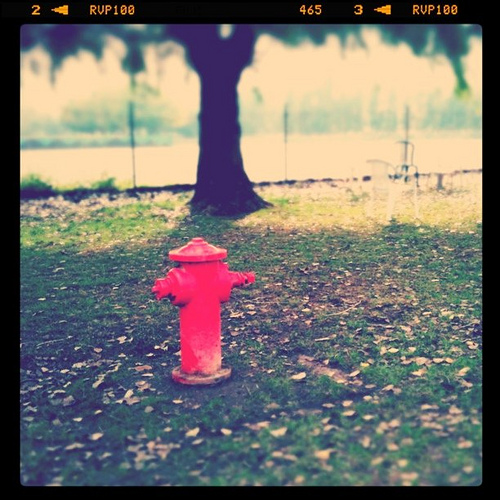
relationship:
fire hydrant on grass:
[142, 232, 260, 391] [20, 171, 482, 484]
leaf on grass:
[291, 373, 306, 383] [20, 171, 482, 484]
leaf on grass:
[271, 426, 286, 440] [20, 171, 482, 484]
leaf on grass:
[218, 426, 235, 437] [20, 171, 482, 484]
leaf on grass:
[185, 424, 200, 438] [20, 171, 482, 484]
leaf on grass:
[88, 431, 99, 443] [20, 171, 482, 484]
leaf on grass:
[315, 446, 332, 463] [20, 171, 482, 484]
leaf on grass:
[412, 369, 426, 376] [20, 171, 482, 484]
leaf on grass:
[457, 435, 472, 456] [20, 171, 482, 484]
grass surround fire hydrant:
[20, 171, 482, 484] [142, 232, 260, 391]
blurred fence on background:
[19, 100, 486, 194] [24, 30, 471, 216]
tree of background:
[22, 24, 486, 221] [24, 30, 471, 216]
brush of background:
[51, 74, 461, 150] [24, 30, 471, 216]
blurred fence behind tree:
[19, 100, 486, 194] [159, 24, 279, 213]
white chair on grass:
[350, 150, 409, 210] [250, 172, 498, 253]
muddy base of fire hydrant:
[169, 360, 234, 387] [142, 232, 260, 391]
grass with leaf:
[20, 171, 482, 484] [452, 406, 465, 417]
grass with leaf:
[20, 171, 482, 484] [408, 368, 429, 381]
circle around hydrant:
[193, 365, 263, 436] [115, 191, 305, 406]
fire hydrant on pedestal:
[142, 232, 260, 391] [167, 364, 246, 387]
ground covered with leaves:
[240, 218, 484, 463] [116, 379, 155, 422]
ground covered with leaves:
[240, 218, 484, 463] [257, 267, 419, 324]